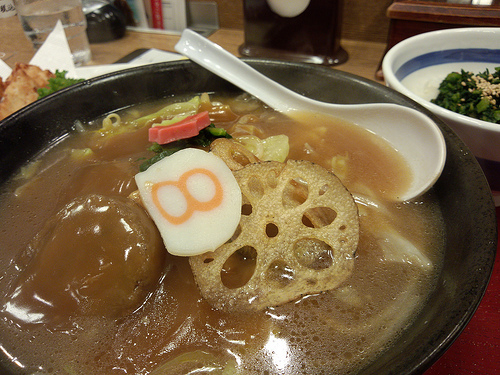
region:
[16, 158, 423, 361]
a delicious looking stew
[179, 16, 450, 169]
A white spoon in a stew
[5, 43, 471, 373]
A black bowl holding stew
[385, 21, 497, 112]
A white bowl holding vegitable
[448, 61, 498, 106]
Green vegitable in a sause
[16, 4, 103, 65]
A glass with water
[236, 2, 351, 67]
A wooden serviette holder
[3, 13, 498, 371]
A wooden cooking table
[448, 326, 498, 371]
A red table Napkin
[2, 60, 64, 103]
A tasty looking sandwhich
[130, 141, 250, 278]
cooked egg with letter eight yolk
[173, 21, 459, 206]
white ceramic soup spoon in pot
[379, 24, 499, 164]
white glass bowl with thin blue stripe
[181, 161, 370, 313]
cooked meat part of pepper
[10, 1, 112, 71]
see through glass of water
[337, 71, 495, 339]
edge of black bowl with soup in it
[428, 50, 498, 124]
green salad in white glass bowl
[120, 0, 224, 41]
mail sitting in envelope holder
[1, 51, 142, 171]
bread sitting next to black bowl of soup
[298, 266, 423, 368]
broth of soup in black bowl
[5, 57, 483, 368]
A bowl with soup in it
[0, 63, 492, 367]
The closest bowl is black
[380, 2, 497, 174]
White bowl with a blue ring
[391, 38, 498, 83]
Blue ring in the white bowl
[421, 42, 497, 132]
Salad in the white bowl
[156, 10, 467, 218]
White spoon in the black bowl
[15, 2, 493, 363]
Nobody shown in the photo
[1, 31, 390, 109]
The table is brown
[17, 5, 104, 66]
Glass of water in the upper left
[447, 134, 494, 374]
Red place mat under the bowl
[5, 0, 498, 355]
a big bowl of Asian soup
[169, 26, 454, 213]
a white spoon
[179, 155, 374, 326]
a brown mushroom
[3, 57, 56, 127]
a delicious brown egg roll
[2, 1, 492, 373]
the meal at a Chinese restaurant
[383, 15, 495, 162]
a bowl full of green vegetables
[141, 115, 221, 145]
a small shaped carrot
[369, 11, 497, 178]
a white bowl with a blue stripe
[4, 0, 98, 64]
a glass of water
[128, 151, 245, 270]
food in the shape of an eight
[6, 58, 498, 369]
a bowl of soup is in a dish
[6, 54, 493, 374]
the bowl is black on the table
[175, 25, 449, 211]
a white spoon is in the bowl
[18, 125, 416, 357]
the soup has a brown gravy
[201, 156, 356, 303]
a vegetable with holes in it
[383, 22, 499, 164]
a white bowl has a blue trim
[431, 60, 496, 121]
green leaves and seeds are in the bowl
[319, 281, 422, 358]
noodles are in the broth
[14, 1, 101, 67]
a glass of water is on the table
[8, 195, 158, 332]
a roundish piece of meat is in the bowl